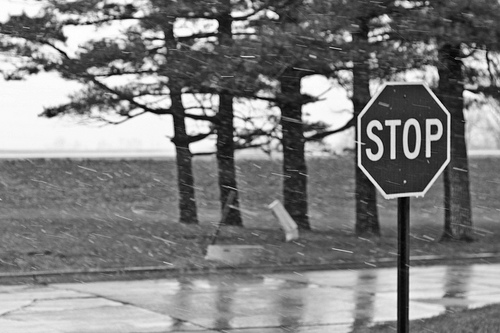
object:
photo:
[0, 0, 500, 333]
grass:
[2, 155, 500, 333]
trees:
[0, 0, 500, 243]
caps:
[365, 118, 446, 161]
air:
[17, 35, 481, 282]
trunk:
[277, 73, 309, 230]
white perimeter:
[447, 114, 452, 161]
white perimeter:
[384, 81, 426, 85]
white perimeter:
[356, 116, 361, 166]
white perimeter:
[384, 194, 424, 197]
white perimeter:
[426, 161, 455, 196]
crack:
[0, 264, 500, 333]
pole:
[394, 195, 410, 333]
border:
[355, 82, 451, 199]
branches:
[5, 11, 164, 121]